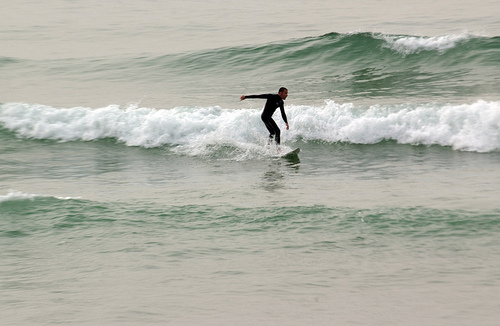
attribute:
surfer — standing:
[239, 86, 290, 157]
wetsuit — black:
[242, 93, 287, 153]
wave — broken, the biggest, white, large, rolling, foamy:
[1, 100, 499, 162]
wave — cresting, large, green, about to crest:
[166, 31, 499, 87]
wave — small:
[1, 188, 500, 259]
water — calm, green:
[0, 0, 497, 92]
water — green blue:
[2, 1, 500, 324]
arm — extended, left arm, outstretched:
[239, 93, 271, 100]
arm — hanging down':
[278, 103, 291, 131]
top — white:
[364, 28, 485, 59]